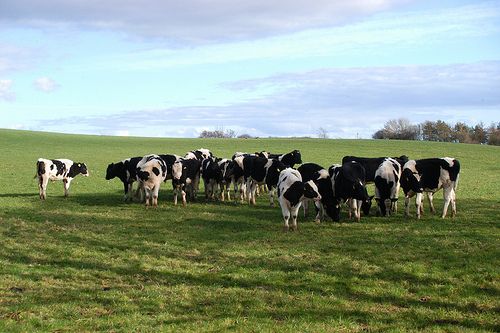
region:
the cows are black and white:
[41, 130, 497, 247]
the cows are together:
[39, 146, 461, 229]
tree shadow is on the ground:
[188, 228, 424, 308]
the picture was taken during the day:
[11, 10, 486, 330]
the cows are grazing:
[26, 138, 462, 230]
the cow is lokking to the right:
[403, 160, 461, 221]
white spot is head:
[412, 171, 421, 180]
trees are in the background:
[381, 120, 498, 147]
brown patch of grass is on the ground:
[39, 216, 71, 238]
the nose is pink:
[313, 193, 324, 202]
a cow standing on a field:
[25, 145, 95, 211]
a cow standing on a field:
[367, 148, 400, 223]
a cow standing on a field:
[325, 157, 375, 227]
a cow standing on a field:
[300, 150, 345, 242]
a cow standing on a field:
[280, 153, 315, 234]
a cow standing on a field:
[227, 147, 280, 203]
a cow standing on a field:
[198, 135, 243, 202]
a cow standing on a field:
[172, 150, 208, 203]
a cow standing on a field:
[130, 145, 175, 203]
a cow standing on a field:
[101, 150, 142, 207]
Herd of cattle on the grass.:
[23, 145, 459, 228]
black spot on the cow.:
[45, 160, 57, 172]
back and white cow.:
[397, 145, 465, 222]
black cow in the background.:
[340, 152, 407, 192]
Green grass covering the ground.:
[2, 128, 499, 331]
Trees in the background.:
[370, 113, 498, 148]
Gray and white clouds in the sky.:
[0, 3, 495, 136]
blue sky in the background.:
[0, 2, 497, 147]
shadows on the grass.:
[5, 198, 496, 332]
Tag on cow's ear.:
[75, 160, 83, 169]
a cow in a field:
[34, 156, 91, 198]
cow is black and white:
[277, 165, 321, 224]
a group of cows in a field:
[106, 145, 461, 224]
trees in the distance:
[369, 119, 499, 149]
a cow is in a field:
[401, 155, 461, 219]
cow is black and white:
[36, 155, 92, 200]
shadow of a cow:
[1, 191, 42, 197]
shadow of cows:
[71, 189, 198, 208]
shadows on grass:
[1, 205, 498, 329]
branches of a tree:
[198, 128, 239, 138]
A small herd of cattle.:
[31, 146, 461, 233]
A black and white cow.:
[401, 155, 465, 222]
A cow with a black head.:
[328, 160, 372, 222]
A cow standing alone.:
[31, 157, 90, 199]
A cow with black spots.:
[134, 152, 167, 209]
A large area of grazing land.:
[0, 128, 499, 331]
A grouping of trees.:
[371, 118, 498, 145]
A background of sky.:
[1, 0, 498, 145]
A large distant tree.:
[315, 123, 333, 137]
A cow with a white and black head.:
[169, 155, 199, 208]